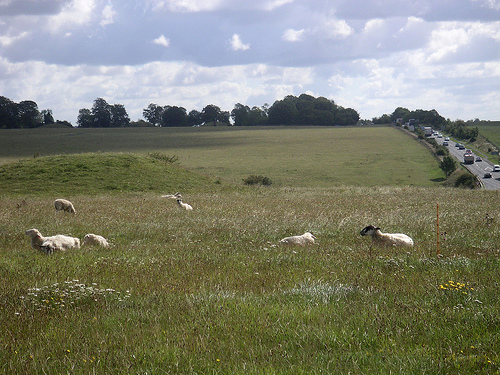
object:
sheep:
[22, 228, 83, 252]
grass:
[0, 121, 499, 375]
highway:
[395, 111, 500, 190]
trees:
[40, 108, 54, 125]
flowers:
[434, 282, 443, 292]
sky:
[0, 0, 499, 125]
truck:
[472, 153, 485, 163]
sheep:
[358, 224, 415, 249]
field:
[0, 120, 497, 375]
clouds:
[0, 0, 500, 120]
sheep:
[277, 228, 315, 249]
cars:
[460, 153, 477, 165]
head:
[360, 224, 375, 234]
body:
[380, 230, 415, 253]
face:
[358, 224, 373, 234]